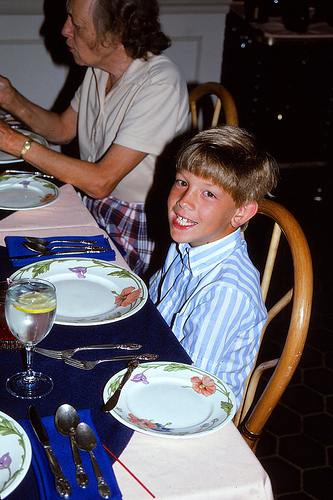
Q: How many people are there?
A: 2.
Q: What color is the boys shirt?
A: Blue and white.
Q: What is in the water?
A: Lemons.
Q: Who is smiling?
A: The boy.